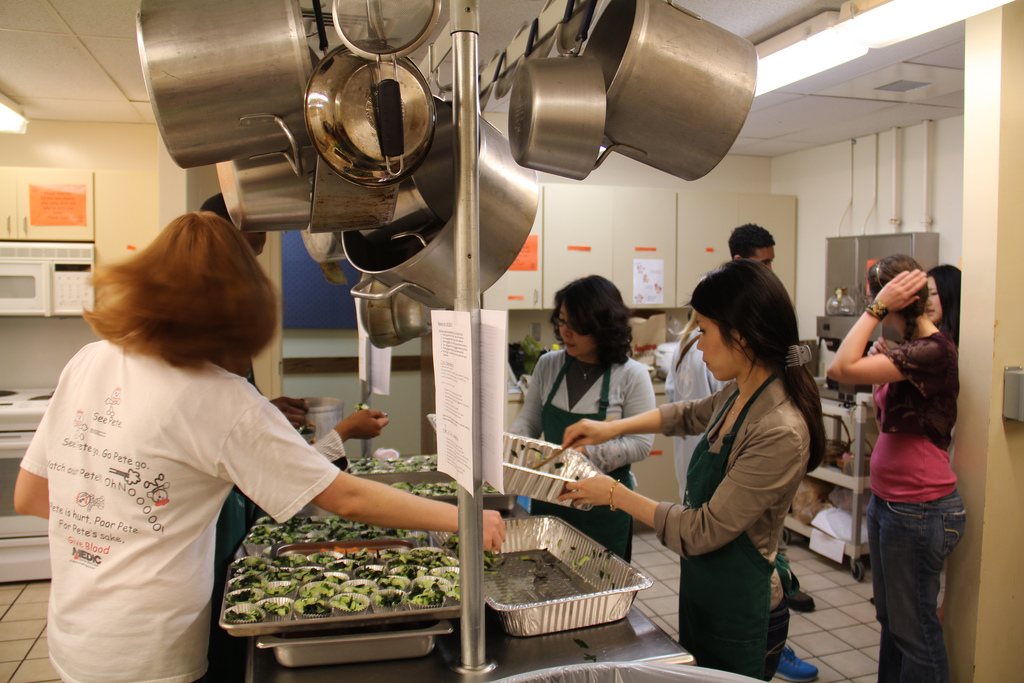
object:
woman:
[13, 210, 509, 683]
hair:
[79, 210, 277, 372]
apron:
[677, 370, 779, 681]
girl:
[510, 275, 655, 564]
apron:
[528, 358, 634, 557]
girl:
[561, 260, 823, 683]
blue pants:
[866, 491, 965, 682]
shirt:
[654, 380, 812, 565]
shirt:
[866, 332, 957, 504]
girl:
[826, 253, 965, 683]